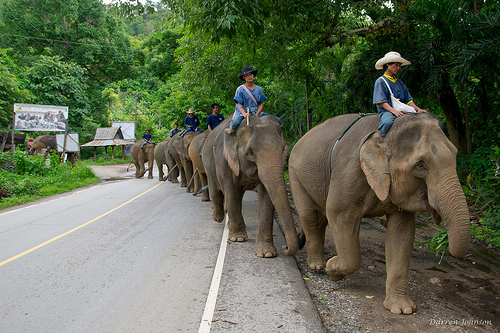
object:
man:
[179, 108, 204, 138]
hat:
[186, 109, 196, 114]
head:
[188, 111, 195, 117]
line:
[0, 180, 165, 265]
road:
[0, 159, 500, 332]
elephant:
[289, 112, 471, 311]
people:
[206, 104, 226, 133]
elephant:
[126, 139, 155, 179]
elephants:
[201, 115, 300, 259]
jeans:
[376, 110, 395, 134]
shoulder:
[375, 74, 404, 85]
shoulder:
[238, 84, 262, 91]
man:
[343, 38, 425, 115]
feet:
[227, 228, 249, 243]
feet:
[255, 242, 280, 258]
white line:
[198, 213, 231, 333]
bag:
[381, 77, 418, 113]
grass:
[415, 133, 500, 264]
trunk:
[427, 166, 470, 258]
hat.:
[239, 66, 259, 81]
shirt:
[206, 114, 225, 131]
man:
[372, 52, 430, 135]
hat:
[375, 51, 411, 70]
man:
[224, 67, 284, 135]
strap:
[330, 112, 380, 182]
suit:
[231, 84, 266, 130]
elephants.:
[189, 129, 211, 201]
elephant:
[169, 130, 196, 188]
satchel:
[379, 76, 417, 113]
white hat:
[375, 51, 411, 70]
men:
[133, 50, 431, 160]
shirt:
[373, 75, 414, 134]